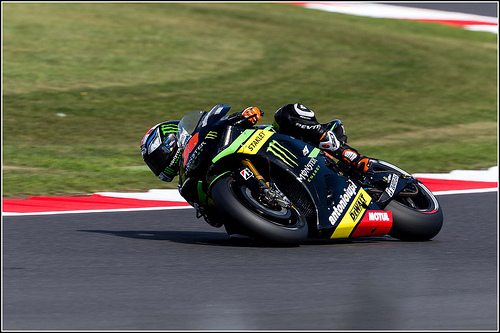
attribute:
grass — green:
[3, 1, 498, 197]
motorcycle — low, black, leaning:
[100, 95, 494, 257]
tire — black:
[208, 176, 304, 247]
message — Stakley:
[242, 126, 272, 159]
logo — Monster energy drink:
[264, 135, 306, 168]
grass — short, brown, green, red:
[0, 19, 432, 106]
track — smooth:
[2, 205, 182, 322]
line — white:
[0, 210, 178, 233]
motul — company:
[361, 212, 393, 224]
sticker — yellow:
[245, 135, 266, 153]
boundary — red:
[3, 176, 144, 223]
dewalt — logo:
[337, 187, 373, 230]